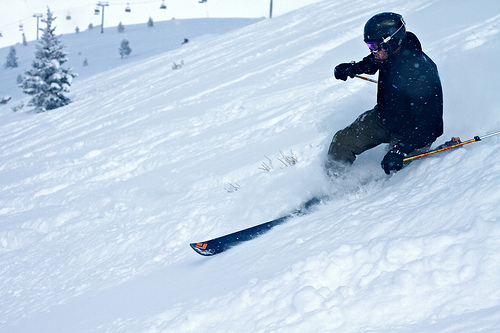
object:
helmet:
[364, 13, 406, 46]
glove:
[333, 62, 362, 81]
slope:
[7, 0, 494, 332]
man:
[326, 12, 462, 181]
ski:
[177, 5, 500, 299]